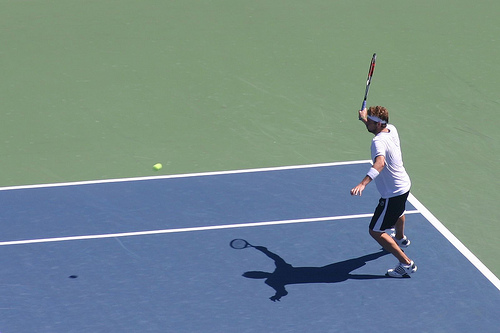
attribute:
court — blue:
[12, 126, 496, 325]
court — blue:
[14, 153, 494, 322]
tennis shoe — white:
[387, 259, 418, 279]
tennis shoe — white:
[389, 233, 411, 247]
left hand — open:
[350, 182, 367, 198]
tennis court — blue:
[2, 163, 498, 331]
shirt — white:
[370, 123, 413, 198]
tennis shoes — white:
[386, 233, 418, 278]